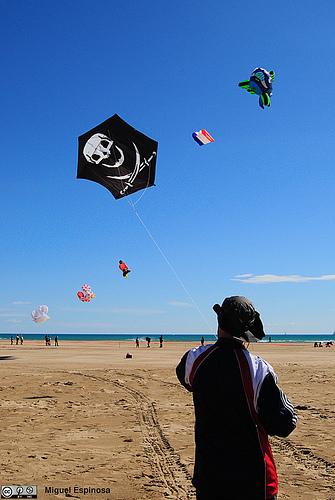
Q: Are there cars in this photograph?
A: No, there are no cars.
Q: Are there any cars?
A: No, there are no cars.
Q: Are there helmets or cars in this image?
A: No, there are no cars or helmets.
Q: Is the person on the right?
A: Yes, the person is on the right of the image.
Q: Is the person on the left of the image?
A: No, the person is on the right of the image.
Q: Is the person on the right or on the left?
A: The person is on the right of the image.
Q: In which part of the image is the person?
A: The person is on the right of the image.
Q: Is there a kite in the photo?
A: Yes, there is a kite.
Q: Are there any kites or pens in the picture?
A: Yes, there is a kite.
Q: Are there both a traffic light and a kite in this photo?
A: No, there is a kite but no traffic lights.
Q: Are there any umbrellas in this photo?
A: No, there are no umbrellas.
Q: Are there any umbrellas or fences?
A: No, there are no umbrellas or fences.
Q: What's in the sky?
A: The kite is in the sky.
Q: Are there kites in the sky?
A: Yes, there is a kite in the sky.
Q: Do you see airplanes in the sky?
A: No, there is a kite in the sky.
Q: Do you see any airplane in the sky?
A: No, there is a kite in the sky.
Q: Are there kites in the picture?
A: Yes, there is a kite.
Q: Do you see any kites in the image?
A: Yes, there is a kite.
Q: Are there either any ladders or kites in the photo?
A: Yes, there is a kite.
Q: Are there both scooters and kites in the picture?
A: No, there is a kite but no scooters.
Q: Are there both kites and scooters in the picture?
A: No, there is a kite but no scooters.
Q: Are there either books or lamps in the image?
A: No, there are no books or lamps.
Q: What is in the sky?
A: The kite is in the sky.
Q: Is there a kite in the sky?
A: Yes, there is a kite in the sky.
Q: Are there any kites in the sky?
A: Yes, there is a kite in the sky.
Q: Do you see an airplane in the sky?
A: No, there is a kite in the sky.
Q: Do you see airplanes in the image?
A: No, there are no airplanes.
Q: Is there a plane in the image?
A: No, there are no airplanes.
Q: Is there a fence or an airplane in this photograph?
A: No, there are no airplanes or fences.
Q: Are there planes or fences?
A: No, there are no planes or fences.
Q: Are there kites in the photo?
A: Yes, there is a kite.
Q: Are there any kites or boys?
A: Yes, there is a kite.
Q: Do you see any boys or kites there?
A: Yes, there is a kite.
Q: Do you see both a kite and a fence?
A: No, there is a kite but no fences.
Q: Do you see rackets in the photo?
A: No, there are no rackets.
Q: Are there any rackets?
A: No, there are no rackets.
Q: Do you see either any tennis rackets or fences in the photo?
A: No, there are no tennis rackets or fences.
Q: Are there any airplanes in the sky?
A: No, there is a kite in the sky.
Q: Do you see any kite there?
A: Yes, there is a kite.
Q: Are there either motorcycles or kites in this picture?
A: Yes, there is a kite.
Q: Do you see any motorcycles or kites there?
A: Yes, there is a kite.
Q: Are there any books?
A: No, there are no books.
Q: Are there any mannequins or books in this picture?
A: No, there are no books or mannequins.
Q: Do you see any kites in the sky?
A: Yes, there is a kite in the sky.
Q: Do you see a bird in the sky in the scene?
A: No, there is a kite in the sky.